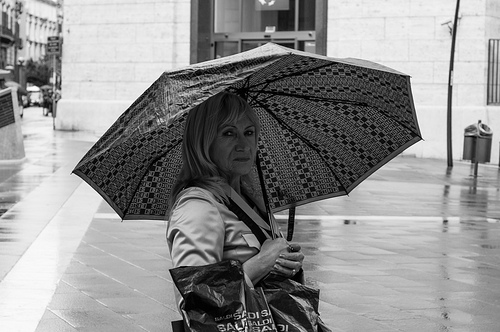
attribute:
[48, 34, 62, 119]
sign — tall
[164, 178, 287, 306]
shirt — long sleeved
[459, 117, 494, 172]
trashcan — public 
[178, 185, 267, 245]
strap — black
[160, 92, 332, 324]
woman — standing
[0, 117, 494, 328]
streets — wet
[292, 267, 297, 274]
band — wedding band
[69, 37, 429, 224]
umbrella — black, white, open